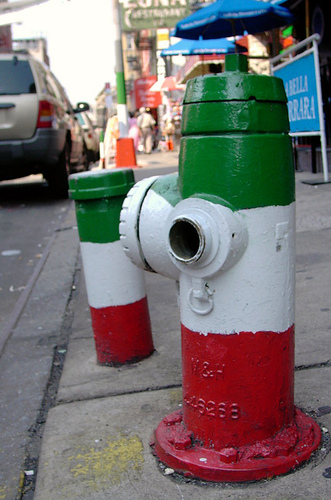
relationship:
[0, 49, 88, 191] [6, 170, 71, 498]
vehicle on road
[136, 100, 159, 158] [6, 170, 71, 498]
person on road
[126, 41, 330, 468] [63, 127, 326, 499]
hydrant on sidewalk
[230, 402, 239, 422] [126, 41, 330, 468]
number on hydrant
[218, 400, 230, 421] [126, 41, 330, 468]
6 on hydrant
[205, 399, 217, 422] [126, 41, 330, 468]
2 on hydrant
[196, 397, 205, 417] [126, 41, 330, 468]
6 on hydrant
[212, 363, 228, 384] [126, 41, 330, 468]
h on hydrant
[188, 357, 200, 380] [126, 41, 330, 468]
h on hydrant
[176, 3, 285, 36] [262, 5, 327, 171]
umbrella by building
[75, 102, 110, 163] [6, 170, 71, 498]
car parked on road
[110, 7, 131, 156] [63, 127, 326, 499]
light pole on sidewalk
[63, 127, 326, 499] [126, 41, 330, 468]
sidewalk by hydrant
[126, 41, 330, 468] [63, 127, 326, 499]
hydrant bolted to sidewalk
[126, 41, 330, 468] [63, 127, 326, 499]
hydrant on top of sidewalk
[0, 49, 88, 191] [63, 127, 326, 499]
vehicle parked by sidewalk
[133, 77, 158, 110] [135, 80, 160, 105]
sign with letters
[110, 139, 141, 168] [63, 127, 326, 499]
block on sidewalk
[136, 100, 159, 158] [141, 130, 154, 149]
person walking in khaki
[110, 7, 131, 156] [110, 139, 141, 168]
light pole with block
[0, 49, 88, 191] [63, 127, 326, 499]
vehicle parked near sidewalk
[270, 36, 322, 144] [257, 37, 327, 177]
sign with frame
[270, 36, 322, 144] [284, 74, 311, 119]
sign with lettering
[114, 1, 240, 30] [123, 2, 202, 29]
sign with letters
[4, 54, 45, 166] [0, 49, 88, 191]
back of vehicle